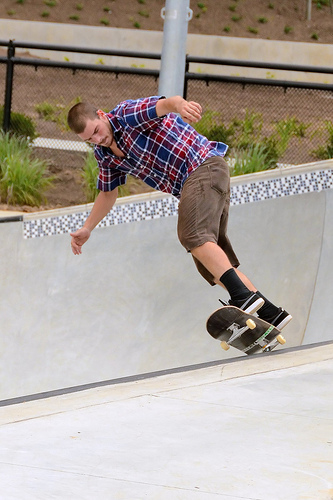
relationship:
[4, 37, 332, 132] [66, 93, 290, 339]
fence behind man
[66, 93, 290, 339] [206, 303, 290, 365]
man on board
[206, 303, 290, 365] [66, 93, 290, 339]
board under man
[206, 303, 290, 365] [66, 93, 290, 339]
board below man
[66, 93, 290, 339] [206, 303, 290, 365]
man above board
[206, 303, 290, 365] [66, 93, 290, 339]
board beside man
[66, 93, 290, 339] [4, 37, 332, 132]
man in front of fence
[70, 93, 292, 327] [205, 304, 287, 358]
man riding skateboard